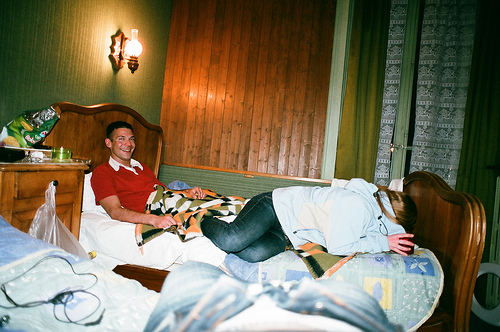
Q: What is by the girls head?
A: Footboard.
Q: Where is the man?
A: Head of the bed.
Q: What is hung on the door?
A: Drapes.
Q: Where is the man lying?
A: On the bed.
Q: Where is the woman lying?
A: On the bed.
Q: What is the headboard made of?
A: Wood.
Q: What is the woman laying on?
A: Quilt.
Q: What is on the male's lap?
A: White and orange quilt.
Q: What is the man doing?
A: Laying in bed.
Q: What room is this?
A: Bedroom.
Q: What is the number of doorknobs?
A: One.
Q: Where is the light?
A: Above bed.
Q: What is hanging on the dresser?
A: A bag.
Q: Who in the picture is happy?
A: The man.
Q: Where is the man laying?
A: In bed.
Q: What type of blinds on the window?
A: Wooden.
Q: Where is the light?
A: Above the man's head.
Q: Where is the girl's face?
A: In the bed.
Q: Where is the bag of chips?
A: On the nightstand.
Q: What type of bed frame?
A: Wooden.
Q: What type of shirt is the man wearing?
A: Polo.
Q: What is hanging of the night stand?
A: Plastic bag.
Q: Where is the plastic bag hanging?
A: Off the night stand.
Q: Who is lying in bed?
A: Couple of people.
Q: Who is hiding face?
A: A woman.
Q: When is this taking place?
A: Taking place at night.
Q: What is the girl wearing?
A: Jeans.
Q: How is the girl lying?
A: Opposite of the man.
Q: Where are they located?
A: Bedroom.